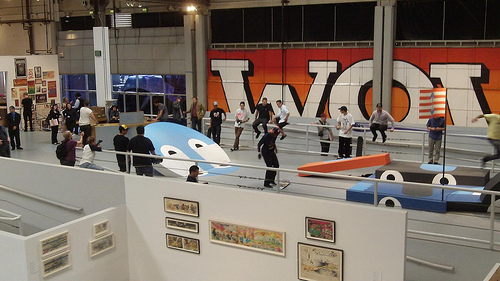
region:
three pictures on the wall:
[145, 193, 204, 259]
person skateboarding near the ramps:
[252, 114, 289, 193]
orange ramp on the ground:
[295, 150, 393, 176]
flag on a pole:
[412, 83, 447, 120]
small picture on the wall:
[300, 210, 342, 244]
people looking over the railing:
[45, 133, 112, 166]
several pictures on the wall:
[10, 54, 57, 88]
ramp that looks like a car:
[382, 164, 493, 191]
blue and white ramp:
[155, 124, 226, 174]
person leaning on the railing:
[228, 93, 250, 155]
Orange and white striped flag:
[416, 83, 447, 120]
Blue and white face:
[137, 113, 230, 177]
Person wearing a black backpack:
[52, 128, 84, 165]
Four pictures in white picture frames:
[36, 219, 117, 277]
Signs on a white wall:
[8, 54, 60, 109]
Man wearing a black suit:
[2, 103, 25, 151]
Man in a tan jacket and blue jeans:
[183, 92, 206, 134]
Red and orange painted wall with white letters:
[207, 44, 498, 128]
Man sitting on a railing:
[367, 100, 397, 141]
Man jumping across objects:
[470, 106, 499, 171]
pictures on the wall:
[155, 195, 205, 256]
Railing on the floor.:
[57, 143, 497, 250]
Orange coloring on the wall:
[207, 48, 497, 133]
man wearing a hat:
[113, 120, 130, 136]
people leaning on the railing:
[53, 128, 108, 170]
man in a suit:
[3, 100, 26, 152]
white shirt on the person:
[72, 97, 99, 130]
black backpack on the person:
[52, 130, 78, 165]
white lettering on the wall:
[207, 55, 497, 136]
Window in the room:
[65, 73, 87, 92]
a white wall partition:
[113, 159, 424, 279]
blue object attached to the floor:
[134, 102, 256, 208]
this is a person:
[109, 105, 139, 173]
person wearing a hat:
[109, 110, 137, 138]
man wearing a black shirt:
[120, 130, 156, 165]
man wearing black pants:
[253, 150, 285, 183]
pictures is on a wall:
[9, 57, 69, 127]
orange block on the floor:
[287, 125, 413, 200]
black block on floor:
[370, 145, 485, 187]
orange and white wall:
[180, 25, 498, 159]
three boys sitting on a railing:
[237, 95, 427, 173]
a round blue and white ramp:
[138, 119, 235, 185]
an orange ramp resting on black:
[294, 149, 404, 176]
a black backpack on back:
[44, 134, 76, 163]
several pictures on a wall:
[147, 187, 384, 279]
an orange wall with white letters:
[210, 42, 498, 139]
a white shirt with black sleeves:
[76, 141, 103, 171]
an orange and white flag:
[393, 84, 458, 129]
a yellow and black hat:
[111, 117, 141, 137]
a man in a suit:
[5, 97, 38, 162]